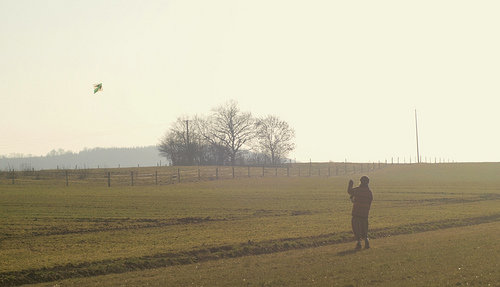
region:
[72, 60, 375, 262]
man flying a kite in field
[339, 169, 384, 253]
man with arm up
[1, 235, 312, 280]
drench in field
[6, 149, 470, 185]
wire gate in background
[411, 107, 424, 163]
pole in background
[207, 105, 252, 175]
leafy tree behind fence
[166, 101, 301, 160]
many trees behind fence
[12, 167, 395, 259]
muddy field for person flying kite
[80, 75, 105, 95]
small kite flying overhead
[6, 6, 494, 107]
cloudy skies overlooking a kite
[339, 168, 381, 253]
a man is flying a kite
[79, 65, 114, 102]
kite is flying by a man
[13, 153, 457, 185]
a fence in the center of a field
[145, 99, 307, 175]
trees in the center of field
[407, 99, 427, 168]
pole on side of fence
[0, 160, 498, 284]
field is cover with green grass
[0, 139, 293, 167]
trees are in the background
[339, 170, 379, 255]
person has shorts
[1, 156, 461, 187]
fence is made of sticks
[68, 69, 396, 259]
kite is far from man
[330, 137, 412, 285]
a man flying a kite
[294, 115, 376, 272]
a man flying a kite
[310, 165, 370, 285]
a man flying a kite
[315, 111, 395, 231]
a man flying a kite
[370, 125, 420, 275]
a man flying a kite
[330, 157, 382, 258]
a man flying a kite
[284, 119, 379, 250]
man flying a kite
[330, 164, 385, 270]
man flying a kite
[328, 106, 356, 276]
man flying a kite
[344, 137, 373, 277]
man flying a kite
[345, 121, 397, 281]
man flying a kite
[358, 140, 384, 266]
man flying a kite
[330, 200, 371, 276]
man flying a kite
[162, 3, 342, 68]
The sky is white.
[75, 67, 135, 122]
The kite is flying.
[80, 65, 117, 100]
A kite is in the air.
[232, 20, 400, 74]
The sky is clear.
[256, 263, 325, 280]
The grass is green.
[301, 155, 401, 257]
The person is in a field.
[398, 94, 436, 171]
A pole is in the background.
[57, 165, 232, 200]
A fence is in the background.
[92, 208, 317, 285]
The grass is short.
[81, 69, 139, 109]
A kite is flying in the sky.